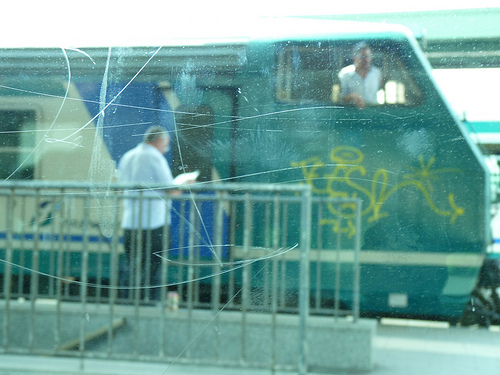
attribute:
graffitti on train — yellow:
[282, 142, 461, 248]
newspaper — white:
[170, 172, 196, 192]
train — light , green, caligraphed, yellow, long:
[0, 36, 489, 314]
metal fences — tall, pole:
[1, 176, 361, 374]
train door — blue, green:
[153, 86, 239, 277]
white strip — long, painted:
[234, 242, 487, 268]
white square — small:
[389, 292, 408, 310]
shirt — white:
[112, 140, 177, 230]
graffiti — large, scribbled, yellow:
[285, 142, 468, 236]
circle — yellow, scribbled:
[333, 142, 365, 170]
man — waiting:
[116, 123, 185, 303]